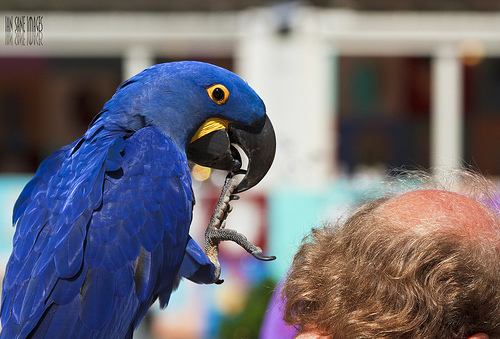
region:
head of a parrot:
[172, 58, 289, 196]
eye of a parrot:
[200, 85, 232, 122]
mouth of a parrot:
[210, 115, 282, 197]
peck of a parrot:
[219, 123, 283, 187]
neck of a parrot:
[82, 83, 200, 164]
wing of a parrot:
[167, 208, 239, 280]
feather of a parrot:
[45, 203, 156, 294]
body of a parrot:
[15, 136, 189, 327]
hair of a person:
[366, 211, 497, 296]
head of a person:
[260, 171, 491, 322]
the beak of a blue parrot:
[198, 130, 320, 188]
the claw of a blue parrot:
[201, 176, 266, 274]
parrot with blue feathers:
[3, 40, 270, 337]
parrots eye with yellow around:
[201, 75, 238, 121]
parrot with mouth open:
[201, 129, 261, 169]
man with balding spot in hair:
[352, 175, 495, 265]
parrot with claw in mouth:
[3, 47, 273, 337]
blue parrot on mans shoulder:
[3, 50, 278, 331]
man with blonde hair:
[280, 229, 467, 336]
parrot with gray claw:
[210, 173, 260, 288]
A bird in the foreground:
[1, 49, 283, 337]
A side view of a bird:
[4, 52, 284, 337]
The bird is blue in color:
[0, 47, 284, 337]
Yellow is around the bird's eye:
[198, 74, 238, 114]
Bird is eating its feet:
[183, 104, 283, 279]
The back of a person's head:
[276, 159, 499, 338]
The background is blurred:
[1, 1, 493, 336]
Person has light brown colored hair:
[272, 179, 497, 337]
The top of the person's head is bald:
[359, 163, 497, 285]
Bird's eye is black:
[201, 77, 233, 112]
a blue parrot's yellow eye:
[205, 84, 230, 102]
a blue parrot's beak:
[187, 115, 277, 190]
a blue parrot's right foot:
[205, 171, 275, 284]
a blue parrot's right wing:
[37, 124, 194, 337]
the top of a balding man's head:
[280, 169, 498, 337]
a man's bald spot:
[371, 190, 498, 241]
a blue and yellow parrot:
[0, 59, 276, 337]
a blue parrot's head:
[101, 61, 276, 193]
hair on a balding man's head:
[282, 166, 497, 337]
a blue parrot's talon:
[255, 248, 277, 265]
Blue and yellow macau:
[1, 57, 277, 337]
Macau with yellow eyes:
[0, 57, 275, 337]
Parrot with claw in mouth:
[3, 61, 278, 336]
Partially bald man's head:
[277, 170, 497, 336]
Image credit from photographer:
[0, 16, 46, 46]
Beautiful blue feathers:
[0, 128, 186, 334]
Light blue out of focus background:
[266, 175, 421, 290]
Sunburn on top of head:
[375, 187, 490, 232]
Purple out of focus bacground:
[255, 278, 303, 336]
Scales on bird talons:
[206, 167, 276, 263]